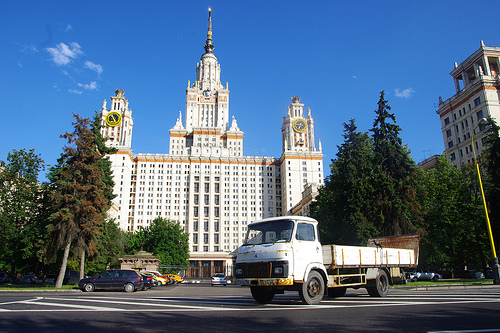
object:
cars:
[140, 272, 168, 287]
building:
[435, 40, 500, 170]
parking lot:
[67, 268, 251, 294]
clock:
[292, 118, 307, 132]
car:
[138, 273, 153, 290]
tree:
[32, 112, 109, 288]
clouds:
[10, 21, 412, 102]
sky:
[0, 0, 500, 69]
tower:
[169, 6, 246, 155]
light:
[468, 116, 500, 285]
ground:
[0, 282, 500, 333]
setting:
[0, 5, 500, 300]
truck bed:
[321, 233, 419, 268]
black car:
[78, 269, 144, 293]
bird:
[369, 240, 382, 250]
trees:
[368, 88, 428, 287]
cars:
[162, 273, 182, 285]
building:
[98, 4, 322, 281]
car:
[209, 273, 228, 287]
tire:
[124, 282, 134, 293]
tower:
[97, 87, 133, 154]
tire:
[367, 269, 390, 297]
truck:
[231, 215, 420, 305]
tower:
[280, 95, 323, 157]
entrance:
[185, 257, 228, 279]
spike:
[203, 5, 215, 56]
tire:
[299, 270, 325, 306]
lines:
[0, 297, 495, 312]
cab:
[231, 215, 324, 290]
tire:
[84, 283, 94, 292]